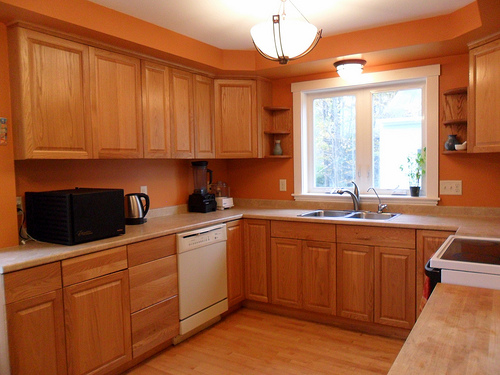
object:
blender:
[188, 161, 217, 213]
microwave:
[24, 187, 126, 246]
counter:
[3, 199, 246, 375]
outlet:
[16, 197, 23, 215]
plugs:
[17, 207, 22, 212]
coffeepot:
[123, 193, 149, 225]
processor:
[212, 181, 233, 210]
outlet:
[141, 186, 147, 199]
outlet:
[279, 179, 286, 191]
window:
[293, 61, 441, 207]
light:
[337, 63, 363, 79]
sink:
[298, 209, 399, 221]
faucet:
[337, 181, 360, 209]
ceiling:
[89, 0, 482, 50]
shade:
[209, 11, 258, 39]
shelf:
[263, 106, 292, 159]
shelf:
[443, 86, 469, 154]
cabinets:
[14, 27, 94, 161]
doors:
[91, 49, 141, 158]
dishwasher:
[177, 223, 230, 333]